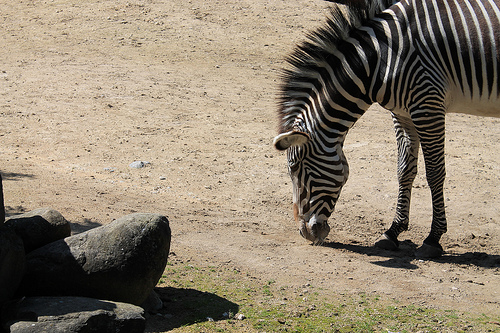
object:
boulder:
[2, 210, 173, 313]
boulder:
[2, 206, 75, 250]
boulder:
[0, 293, 150, 333]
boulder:
[0, 307, 116, 333]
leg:
[414, 75, 449, 230]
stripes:
[378, 72, 413, 95]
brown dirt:
[0, 0, 499, 333]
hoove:
[415, 244, 446, 264]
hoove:
[370, 232, 398, 251]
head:
[275, 117, 351, 246]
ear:
[271, 128, 309, 151]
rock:
[128, 160, 147, 170]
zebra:
[272, 0, 499, 259]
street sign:
[41, 60, 244, 130]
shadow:
[329, 245, 499, 272]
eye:
[290, 163, 300, 173]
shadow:
[0, 164, 42, 182]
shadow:
[1, 202, 101, 243]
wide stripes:
[296, 17, 382, 138]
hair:
[276, 1, 379, 136]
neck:
[268, 26, 383, 166]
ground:
[2, 0, 496, 332]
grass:
[140, 259, 500, 333]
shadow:
[151, 278, 231, 325]